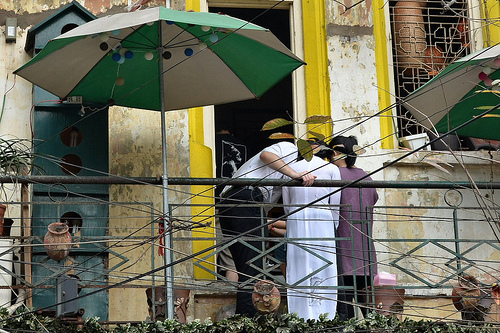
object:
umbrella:
[10, 5, 300, 111]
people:
[329, 135, 380, 319]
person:
[281, 130, 338, 321]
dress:
[280, 158, 341, 321]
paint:
[301, 6, 328, 45]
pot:
[43, 222, 71, 264]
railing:
[80, 177, 161, 185]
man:
[225, 132, 297, 316]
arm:
[258, 150, 292, 174]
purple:
[343, 178, 361, 203]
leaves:
[297, 138, 315, 162]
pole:
[156, 55, 182, 322]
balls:
[160, 50, 174, 62]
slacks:
[216, 196, 272, 276]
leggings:
[343, 278, 359, 315]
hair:
[334, 136, 358, 168]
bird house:
[26, 0, 112, 329]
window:
[389, 0, 486, 149]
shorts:
[231, 236, 272, 285]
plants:
[0, 134, 45, 190]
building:
[293, 0, 500, 330]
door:
[194, 2, 301, 278]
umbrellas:
[402, 39, 500, 146]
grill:
[404, 8, 451, 47]